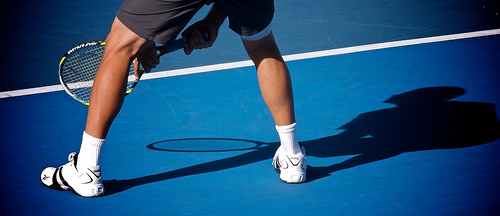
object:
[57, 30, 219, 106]
racket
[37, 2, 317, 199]
man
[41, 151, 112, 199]
shoe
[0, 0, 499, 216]
court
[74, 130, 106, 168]
sock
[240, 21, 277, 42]
wrap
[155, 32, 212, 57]
bottom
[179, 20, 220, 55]
hand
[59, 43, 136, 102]
strings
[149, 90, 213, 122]
surface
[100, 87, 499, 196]
shade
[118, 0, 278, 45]
short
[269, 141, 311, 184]
foot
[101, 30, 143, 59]
knee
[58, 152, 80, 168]
lace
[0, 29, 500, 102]
ilnes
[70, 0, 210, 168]
leg